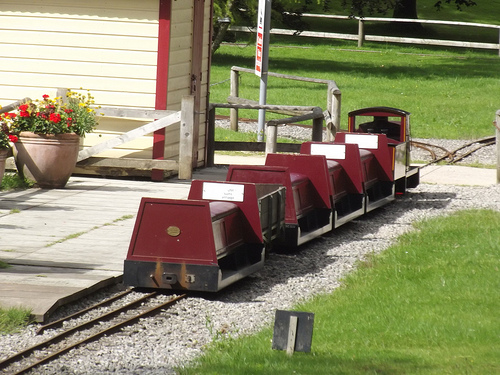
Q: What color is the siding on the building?
A: Cream.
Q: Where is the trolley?
A: On the rails.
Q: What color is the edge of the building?
A: Red.